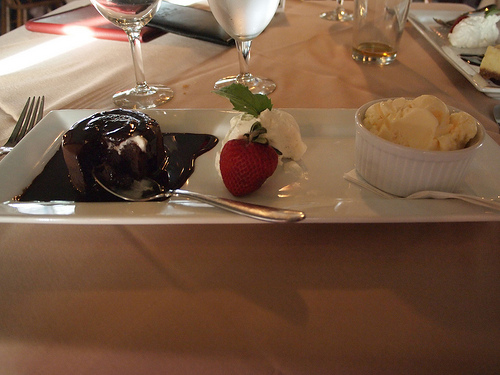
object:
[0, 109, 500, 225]
platter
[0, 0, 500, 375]
table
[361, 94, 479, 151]
desserts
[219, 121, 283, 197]
strawberry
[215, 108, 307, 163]
whipped cream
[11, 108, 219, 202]
chocolate mousse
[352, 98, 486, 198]
bowl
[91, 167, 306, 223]
spoon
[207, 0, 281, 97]
water glass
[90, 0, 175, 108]
wine glass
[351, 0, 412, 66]
glass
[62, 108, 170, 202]
chocolate cake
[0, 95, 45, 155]
fork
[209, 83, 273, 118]
mint leaf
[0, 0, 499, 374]
tablecloth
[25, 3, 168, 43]
tablet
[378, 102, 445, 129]
ramekin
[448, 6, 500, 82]
desserts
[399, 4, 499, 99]
platter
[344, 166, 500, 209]
napkin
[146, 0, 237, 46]
case